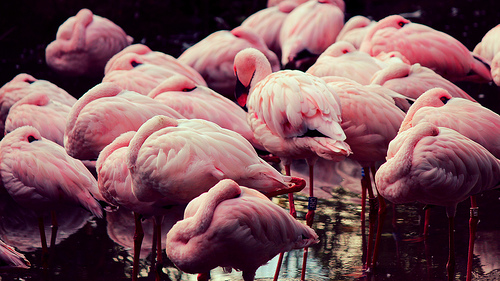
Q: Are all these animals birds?
A: Yes, all the animals are birds.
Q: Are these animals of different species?
A: No, all the animals are birds.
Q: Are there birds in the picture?
A: Yes, there is a bird.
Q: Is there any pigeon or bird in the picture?
A: Yes, there is a bird.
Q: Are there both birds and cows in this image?
A: No, there is a bird but no cows.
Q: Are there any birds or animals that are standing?
A: Yes, the bird is standing.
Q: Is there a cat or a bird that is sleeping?
A: Yes, the bird is sleeping.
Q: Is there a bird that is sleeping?
A: Yes, there is a bird that is sleeping.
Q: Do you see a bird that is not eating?
A: Yes, there is a bird that is sleeping .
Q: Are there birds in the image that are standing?
A: Yes, there is a bird that is standing.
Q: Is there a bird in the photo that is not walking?
A: Yes, there is a bird that is standing.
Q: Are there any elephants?
A: No, there are no elephants.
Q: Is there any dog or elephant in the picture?
A: No, there are no elephants or dogs.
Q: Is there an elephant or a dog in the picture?
A: No, there are no elephants or dogs.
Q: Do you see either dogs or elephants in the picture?
A: No, there are no elephants or dogs.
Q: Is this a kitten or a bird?
A: This is a bird.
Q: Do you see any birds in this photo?
A: Yes, there is a bird.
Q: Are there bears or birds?
A: Yes, there is a bird.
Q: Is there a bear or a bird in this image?
A: Yes, there is a bird.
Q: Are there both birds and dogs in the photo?
A: No, there is a bird but no dogs.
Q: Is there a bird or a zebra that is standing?
A: Yes, the bird is standing.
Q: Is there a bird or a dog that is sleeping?
A: Yes, the bird is sleeping.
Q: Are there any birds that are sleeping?
A: Yes, there is a bird that is sleeping.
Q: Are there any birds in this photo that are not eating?
A: Yes, there is a bird that is sleeping.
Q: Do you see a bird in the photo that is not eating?
A: Yes, there is a bird that is sleeping .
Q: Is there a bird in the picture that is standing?
A: Yes, there is a bird that is standing.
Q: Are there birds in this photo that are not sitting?
A: Yes, there is a bird that is standing.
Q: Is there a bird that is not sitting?
A: Yes, there is a bird that is standing.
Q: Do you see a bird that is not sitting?
A: Yes, there is a bird that is standing .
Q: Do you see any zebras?
A: No, there are no zebras.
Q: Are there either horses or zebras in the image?
A: No, there are no zebras or horses.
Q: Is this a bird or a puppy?
A: This is a bird.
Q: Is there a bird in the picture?
A: Yes, there is a bird.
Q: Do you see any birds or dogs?
A: Yes, there is a bird.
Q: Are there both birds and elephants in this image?
A: No, there is a bird but no elephants.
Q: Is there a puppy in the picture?
A: No, there are no puppies.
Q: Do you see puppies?
A: No, there are no puppies.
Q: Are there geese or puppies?
A: No, there are no puppies or geese.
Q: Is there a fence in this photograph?
A: No, there are no fences.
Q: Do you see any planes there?
A: No, there are no planes.